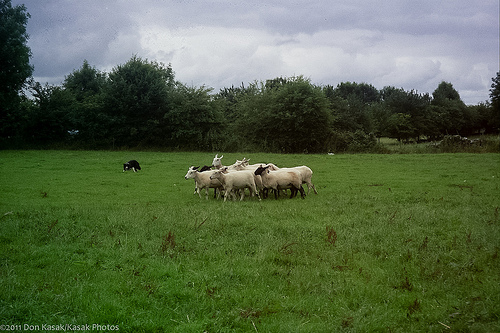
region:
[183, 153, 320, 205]
Flock of sheep walking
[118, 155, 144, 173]
Black and white border collie dog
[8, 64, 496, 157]
Line of trees in background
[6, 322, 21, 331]
Year the photo was taken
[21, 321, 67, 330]
Name of photographer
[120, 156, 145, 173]
Border collie herding sheep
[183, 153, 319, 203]
Flock of sheep being herded by dog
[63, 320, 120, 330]
Business name of photographer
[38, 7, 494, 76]
A sky full of clouds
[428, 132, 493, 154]
A stack of cut wood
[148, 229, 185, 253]
brown bushes on the grass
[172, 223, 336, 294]
green grass in the meadow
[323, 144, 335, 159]
white stack on the grass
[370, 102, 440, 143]
small green trees in the vista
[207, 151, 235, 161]
horns on top of animal's head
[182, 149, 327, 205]
cluster of white animals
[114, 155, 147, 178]
black animal away from the pack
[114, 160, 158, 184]
animal grazing in the field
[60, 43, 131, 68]
approaching rain clouds in the sky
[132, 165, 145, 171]
white feet on black animal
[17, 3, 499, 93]
cloud cover in sky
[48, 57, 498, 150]
line of trees on horizon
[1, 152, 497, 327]
green grass of pasture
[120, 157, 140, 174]
black and white animal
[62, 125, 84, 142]
patch of sky in trees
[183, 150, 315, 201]
herd of walking sheep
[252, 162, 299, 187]
sheep with black face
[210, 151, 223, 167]
sheep with pointy ears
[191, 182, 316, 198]
legs of walking sheep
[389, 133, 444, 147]
shadow under tree on grass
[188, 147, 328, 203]
group of goats in field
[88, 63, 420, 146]
lot of trees with branches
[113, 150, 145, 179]
a black colour animal in the grass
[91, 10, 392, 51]
a sky with clouds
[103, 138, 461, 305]
green grass with group of goats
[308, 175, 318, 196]
a leg of the goat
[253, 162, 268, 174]
a goats black colour face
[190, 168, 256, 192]
white colour goats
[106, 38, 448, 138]
trees and clouds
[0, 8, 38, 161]
a big tree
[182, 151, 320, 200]
Many goats are in a group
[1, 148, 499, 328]
Goats are standing on large grassy field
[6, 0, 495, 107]
Many white clouds are in the sky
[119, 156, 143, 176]
One black animal is standing alone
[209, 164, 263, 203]
One goat has four legs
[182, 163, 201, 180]
The goat has horns on its head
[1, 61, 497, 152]
Many trees are in the background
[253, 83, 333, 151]
A tree has many green leaves on it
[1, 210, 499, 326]
This section of the grass is very long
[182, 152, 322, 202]
This group of goats is huddled together